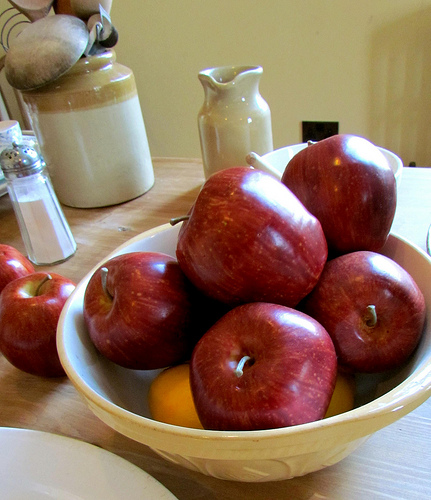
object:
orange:
[149, 363, 205, 429]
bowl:
[55, 217, 431, 483]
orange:
[324, 372, 354, 418]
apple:
[280, 133, 398, 259]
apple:
[170, 166, 328, 309]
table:
[0, 155, 431, 500]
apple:
[82, 252, 200, 370]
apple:
[0, 273, 75, 379]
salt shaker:
[0, 139, 77, 266]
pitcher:
[196, 65, 275, 180]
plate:
[0, 428, 176, 500]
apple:
[188, 302, 338, 430]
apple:
[307, 251, 427, 375]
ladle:
[5, 14, 90, 91]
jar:
[19, 46, 154, 209]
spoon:
[9, 0, 54, 23]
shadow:
[369, 0, 428, 166]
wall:
[0, 0, 431, 168]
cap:
[0, 120, 78, 266]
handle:
[245, 151, 283, 181]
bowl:
[246, 140, 403, 182]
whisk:
[0, 7, 34, 54]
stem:
[170, 215, 190, 226]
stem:
[99, 267, 113, 301]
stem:
[234, 356, 251, 379]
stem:
[366, 305, 378, 327]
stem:
[35, 275, 52, 296]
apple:
[0, 242, 35, 294]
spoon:
[75, 0, 120, 55]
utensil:
[79, 6, 119, 57]